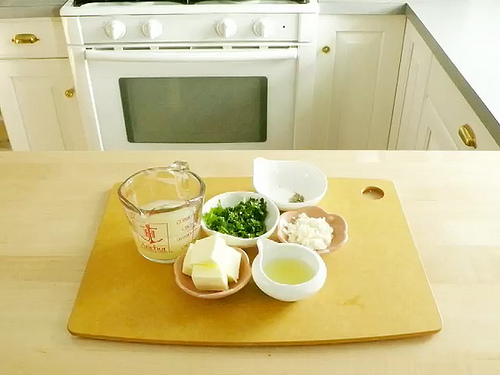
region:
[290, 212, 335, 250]
Rice in the white bowl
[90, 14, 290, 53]
Four knobs on the stove.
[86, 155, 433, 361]
The food is sitting on the cutting board.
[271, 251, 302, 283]
Liquid in the bowl.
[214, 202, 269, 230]
Green food in the bowl.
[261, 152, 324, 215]
The bowl is white.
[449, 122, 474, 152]
The handle on the cabinet is gold.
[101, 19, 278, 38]
white stove control knobs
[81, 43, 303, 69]
white metal oven door handle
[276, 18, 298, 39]
power light on front of stove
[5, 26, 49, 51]
gold metal drawer handle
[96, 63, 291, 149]
viewing window on front of oven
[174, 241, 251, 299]
bowl filled with butter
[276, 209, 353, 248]
sliced onion in bowl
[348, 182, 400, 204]
small hole in brown cutting board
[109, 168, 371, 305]
ingredients sitting on cutting board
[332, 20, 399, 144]
white kitchen cabinet door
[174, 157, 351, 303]
food in bowls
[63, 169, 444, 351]
cutting board holding food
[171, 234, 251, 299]
butter in bowl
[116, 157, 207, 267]
a measuring cup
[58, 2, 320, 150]
a white stove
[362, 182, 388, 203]
a hole on board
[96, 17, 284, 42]
knobs on stove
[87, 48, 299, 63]
handle on stove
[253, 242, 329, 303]
liquid in bowl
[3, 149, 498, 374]
an oak wood counter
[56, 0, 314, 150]
White oven in the kitchen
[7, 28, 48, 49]
Golden drawer pull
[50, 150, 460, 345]
Six ingredients for a recipe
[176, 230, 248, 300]
Butter cubes in the beige bowl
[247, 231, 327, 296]
Oil in the white bowl with a spout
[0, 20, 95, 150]
White kitchen cabinets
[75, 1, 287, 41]
Four knobs to regulate stove temperatore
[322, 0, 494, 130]
Grey laminated countertop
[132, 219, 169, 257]
Symbol of an anchor on the cup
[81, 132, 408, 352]
ingredients for a recipe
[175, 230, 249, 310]
slabs of butter in a bole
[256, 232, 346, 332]
yellow liquid in a bowl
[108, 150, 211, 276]
glass measuring cup with liquid in it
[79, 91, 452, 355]
ingredients on a chopping board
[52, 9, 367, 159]
white oven in a kitchen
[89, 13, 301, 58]
four knobs on an oven